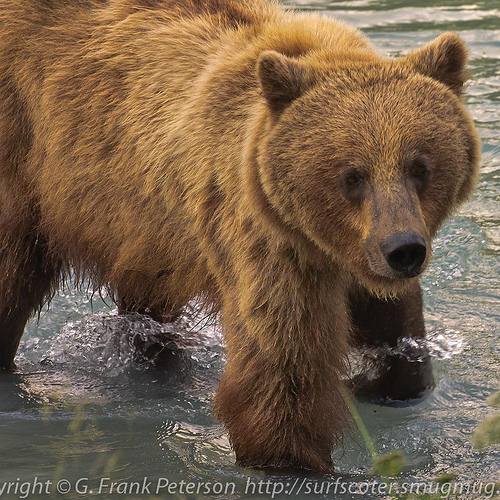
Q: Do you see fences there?
A: No, there are no fences.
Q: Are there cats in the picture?
A: No, there are no cats.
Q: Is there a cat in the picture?
A: No, there are no cats.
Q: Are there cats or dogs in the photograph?
A: No, there are no cats or dogs.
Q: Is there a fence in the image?
A: No, there are no fences.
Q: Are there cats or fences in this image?
A: No, there are no fences or cats.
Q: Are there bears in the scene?
A: Yes, there is a bear.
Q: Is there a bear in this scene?
A: Yes, there is a bear.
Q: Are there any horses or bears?
A: Yes, there is a bear.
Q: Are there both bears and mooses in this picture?
A: No, there is a bear but no mooses.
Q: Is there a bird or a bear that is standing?
A: Yes, the bear is standing.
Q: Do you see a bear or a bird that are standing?
A: Yes, the bear is standing.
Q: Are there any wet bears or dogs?
A: Yes, there is a wet bear.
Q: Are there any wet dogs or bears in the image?
A: Yes, there is a wet bear.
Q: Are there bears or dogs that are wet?
A: Yes, the bear is wet.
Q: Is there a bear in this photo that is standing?
A: Yes, there is a bear that is standing.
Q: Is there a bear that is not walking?
A: Yes, there is a bear that is standing.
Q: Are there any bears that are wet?
A: Yes, there is a wet bear.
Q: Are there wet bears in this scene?
A: Yes, there is a wet bear.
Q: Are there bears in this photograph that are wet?
A: Yes, there is a bear that is wet.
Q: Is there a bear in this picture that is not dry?
A: Yes, there is a wet bear.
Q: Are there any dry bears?
A: Yes, there is a dry bear.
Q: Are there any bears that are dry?
A: Yes, there is a bear that is dry.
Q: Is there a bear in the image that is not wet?
A: Yes, there is a dry bear.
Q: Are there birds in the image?
A: No, there are no birds.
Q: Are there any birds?
A: No, there are no birds.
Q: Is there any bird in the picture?
A: No, there are no birds.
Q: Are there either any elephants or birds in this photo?
A: No, there are no birds or elephants.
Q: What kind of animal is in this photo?
A: The animal is a bear.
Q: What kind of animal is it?
A: The animal is a bear.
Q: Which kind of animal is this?
A: This is a bear.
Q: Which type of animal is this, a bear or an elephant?
A: This is a bear.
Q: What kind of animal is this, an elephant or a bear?
A: This is a bear.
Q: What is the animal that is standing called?
A: The animal is a bear.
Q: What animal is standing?
A: The animal is a bear.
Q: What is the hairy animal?
A: The animal is a bear.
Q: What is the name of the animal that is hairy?
A: The animal is a bear.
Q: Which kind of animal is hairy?
A: The animal is a bear.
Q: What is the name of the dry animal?
A: The animal is a bear.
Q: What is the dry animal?
A: The animal is a bear.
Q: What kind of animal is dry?
A: The animal is a bear.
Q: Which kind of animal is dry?
A: The animal is a bear.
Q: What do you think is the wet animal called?
A: The animal is a bear.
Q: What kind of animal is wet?
A: The animal is a bear.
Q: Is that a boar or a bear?
A: That is a bear.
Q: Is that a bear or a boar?
A: That is a bear.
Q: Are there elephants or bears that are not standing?
A: No, there is a bear but it is standing.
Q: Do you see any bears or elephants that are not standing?
A: No, there is a bear but it is standing.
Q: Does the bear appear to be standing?
A: Yes, the bear is standing.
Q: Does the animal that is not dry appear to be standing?
A: Yes, the bear is standing.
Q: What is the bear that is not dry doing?
A: The bear is standing.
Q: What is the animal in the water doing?
A: The bear is standing.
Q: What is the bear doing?
A: The bear is standing.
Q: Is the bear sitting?
A: No, the bear is standing.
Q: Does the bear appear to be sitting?
A: No, the bear is standing.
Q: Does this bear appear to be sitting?
A: No, the bear is standing.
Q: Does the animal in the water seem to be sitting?
A: No, the bear is standing.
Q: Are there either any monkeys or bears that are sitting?
A: No, there is a bear but it is standing.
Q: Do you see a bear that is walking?
A: No, there is a bear but it is standing.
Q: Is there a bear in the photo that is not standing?
A: No, there is a bear but it is standing.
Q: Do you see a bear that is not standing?
A: No, there is a bear but it is standing.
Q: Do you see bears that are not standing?
A: No, there is a bear but it is standing.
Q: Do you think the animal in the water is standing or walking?
A: The bear is standing.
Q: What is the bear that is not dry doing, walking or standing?
A: The bear is standing.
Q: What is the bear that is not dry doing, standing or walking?
A: The bear is standing.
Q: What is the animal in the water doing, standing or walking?
A: The bear is standing.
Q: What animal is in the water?
A: The animal is a bear.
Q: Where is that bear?
A: The bear is in the water.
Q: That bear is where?
A: The bear is in the water.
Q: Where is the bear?
A: The bear is in the water.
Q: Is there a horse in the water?
A: No, there is a bear in the water.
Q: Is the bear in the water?
A: Yes, the bear is in the water.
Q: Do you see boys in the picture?
A: No, there are no boys.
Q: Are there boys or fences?
A: No, there are no boys or fences.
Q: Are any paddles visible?
A: No, there are no paddles.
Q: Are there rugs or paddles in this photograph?
A: No, there are no paddles or rugs.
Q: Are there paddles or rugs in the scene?
A: No, there are no paddles or rugs.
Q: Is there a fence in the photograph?
A: No, there are no fences.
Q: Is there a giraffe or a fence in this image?
A: No, there are no fences or giraffes.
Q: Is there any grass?
A: Yes, there is grass.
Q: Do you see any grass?
A: Yes, there is grass.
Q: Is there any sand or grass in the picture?
A: Yes, there is grass.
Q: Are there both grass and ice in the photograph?
A: No, there is grass but no ice.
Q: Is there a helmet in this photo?
A: No, there are no helmets.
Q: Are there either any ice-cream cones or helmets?
A: No, there are no helmets or ice-cream cones.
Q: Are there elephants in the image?
A: No, there are no elephants.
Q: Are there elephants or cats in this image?
A: No, there are no elephants or cats.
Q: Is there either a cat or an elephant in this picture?
A: No, there are no elephants or cats.